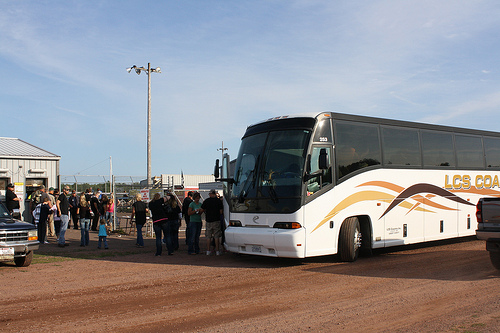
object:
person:
[130, 193, 149, 248]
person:
[77, 194, 91, 247]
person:
[56, 185, 69, 247]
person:
[200, 190, 224, 257]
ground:
[1, 211, 498, 331]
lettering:
[445, 175, 500, 191]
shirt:
[189, 202, 202, 223]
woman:
[187, 193, 206, 255]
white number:
[319, 137, 327, 142]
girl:
[97, 219, 110, 250]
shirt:
[98, 224, 107, 237]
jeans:
[98, 236, 108, 248]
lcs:
[445, 175, 471, 190]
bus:
[213, 110, 498, 262]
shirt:
[132, 201, 148, 222]